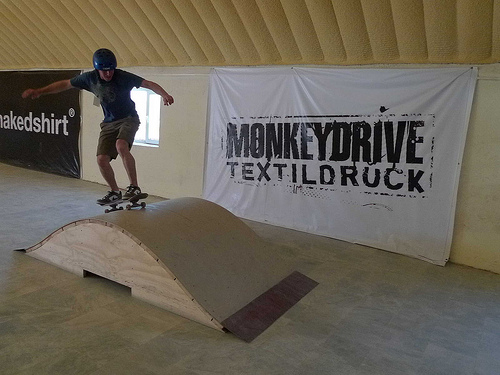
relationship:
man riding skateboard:
[74, 53, 212, 230] [111, 176, 168, 228]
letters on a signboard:
[0, 102, 77, 139] [0, 68, 81, 179]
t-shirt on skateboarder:
[68, 62, 143, 124] [20, 47, 176, 203]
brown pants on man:
[89, 117, 147, 161] [19, 48, 175, 206]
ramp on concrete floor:
[14, 192, 327, 349] [0, 162, 497, 372]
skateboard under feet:
[96, 193, 150, 213] [96, 184, 143, 201]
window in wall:
[125, 81, 165, 153] [15, 53, 498, 270]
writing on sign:
[215, 104, 443, 209] [200, 63, 477, 265]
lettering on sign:
[5, 105, 74, 147] [1, 78, 85, 170]